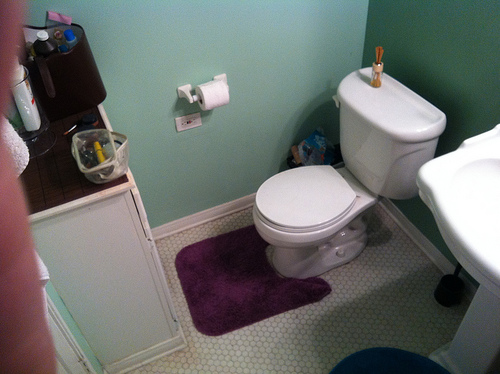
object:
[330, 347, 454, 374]
mat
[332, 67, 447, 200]
tank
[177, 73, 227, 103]
hanger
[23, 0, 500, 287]
wall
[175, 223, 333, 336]
mat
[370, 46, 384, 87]
fragrance dispenser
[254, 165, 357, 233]
lid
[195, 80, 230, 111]
napkin roll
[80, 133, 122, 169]
cosmetics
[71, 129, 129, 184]
bag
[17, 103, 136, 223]
counter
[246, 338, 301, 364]
honeycomb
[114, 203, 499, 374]
floor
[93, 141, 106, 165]
mascara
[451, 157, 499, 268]
sink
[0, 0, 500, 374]
bathroom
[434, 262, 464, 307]
toilet brush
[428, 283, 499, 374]
rack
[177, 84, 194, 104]
dispenser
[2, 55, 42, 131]
bottles